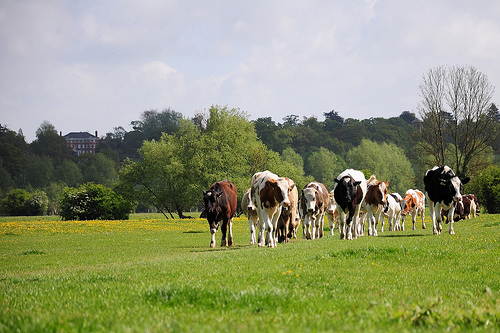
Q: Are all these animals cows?
A: Yes, all the animals are cows.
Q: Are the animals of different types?
A: No, all the animals are cows.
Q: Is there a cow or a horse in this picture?
A: Yes, there is a cow.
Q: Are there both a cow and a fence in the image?
A: No, there is a cow but no fences.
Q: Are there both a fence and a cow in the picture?
A: No, there is a cow but no fences.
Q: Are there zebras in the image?
A: No, there are no zebras.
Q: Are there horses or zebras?
A: No, there are no zebras or horses.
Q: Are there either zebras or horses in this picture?
A: No, there are no zebras or horses.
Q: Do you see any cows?
A: Yes, there is a cow.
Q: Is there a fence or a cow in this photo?
A: Yes, there is a cow.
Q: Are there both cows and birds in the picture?
A: No, there is a cow but no birds.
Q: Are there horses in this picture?
A: No, there are no horses.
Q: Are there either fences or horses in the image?
A: No, there are no horses or fences.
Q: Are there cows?
A: Yes, there is a cow.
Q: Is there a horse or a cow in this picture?
A: Yes, there is a cow.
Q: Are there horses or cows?
A: Yes, there is a cow.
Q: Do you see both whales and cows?
A: No, there is a cow but no whales.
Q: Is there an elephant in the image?
A: No, there are no elephants.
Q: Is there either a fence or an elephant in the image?
A: No, there are no elephants or fences.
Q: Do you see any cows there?
A: Yes, there is a cow.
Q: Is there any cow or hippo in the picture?
A: Yes, there is a cow.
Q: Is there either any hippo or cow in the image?
A: Yes, there is a cow.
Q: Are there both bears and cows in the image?
A: No, there is a cow but no bears.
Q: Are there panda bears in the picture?
A: No, there are no panda bears.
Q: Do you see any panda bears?
A: No, there are no panda bears.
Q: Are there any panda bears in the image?
A: No, there are no panda bears.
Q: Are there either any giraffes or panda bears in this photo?
A: No, there are no panda bears or giraffes.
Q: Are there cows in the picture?
A: Yes, there is a cow.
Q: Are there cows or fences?
A: Yes, there is a cow.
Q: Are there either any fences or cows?
A: Yes, there is a cow.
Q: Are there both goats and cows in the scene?
A: No, there is a cow but no goats.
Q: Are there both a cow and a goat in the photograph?
A: No, there is a cow but no goats.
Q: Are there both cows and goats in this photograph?
A: No, there is a cow but no goats.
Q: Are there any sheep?
A: No, there are no sheep.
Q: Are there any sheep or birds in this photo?
A: No, there are no sheep or birds.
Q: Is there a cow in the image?
A: Yes, there is a cow.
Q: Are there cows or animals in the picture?
A: Yes, there is a cow.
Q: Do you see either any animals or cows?
A: Yes, there is a cow.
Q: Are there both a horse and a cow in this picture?
A: No, there is a cow but no horses.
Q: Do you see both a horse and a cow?
A: No, there is a cow but no horses.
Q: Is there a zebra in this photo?
A: No, there are no zebras.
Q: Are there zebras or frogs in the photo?
A: No, there are no zebras or frogs.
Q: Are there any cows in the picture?
A: Yes, there is a cow.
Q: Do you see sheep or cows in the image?
A: Yes, there is a cow.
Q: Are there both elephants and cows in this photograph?
A: No, there is a cow but no elephants.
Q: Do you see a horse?
A: No, there are no horses.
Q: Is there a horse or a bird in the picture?
A: No, there are no horses or birds.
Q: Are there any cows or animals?
A: Yes, there is a cow.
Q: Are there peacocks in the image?
A: No, there are no peacocks.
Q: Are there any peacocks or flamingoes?
A: No, there are no peacocks or flamingoes.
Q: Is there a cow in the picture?
A: Yes, there is a cow.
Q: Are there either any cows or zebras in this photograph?
A: Yes, there is a cow.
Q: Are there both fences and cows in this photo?
A: No, there is a cow but no fences.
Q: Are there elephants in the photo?
A: No, there are no elephants.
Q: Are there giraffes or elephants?
A: No, there are no elephants or giraffes.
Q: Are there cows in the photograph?
A: Yes, there is a cow.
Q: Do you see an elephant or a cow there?
A: Yes, there is a cow.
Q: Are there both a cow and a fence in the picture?
A: No, there is a cow but no fences.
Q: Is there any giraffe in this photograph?
A: No, there are no giraffes.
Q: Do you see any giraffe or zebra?
A: No, there are no giraffes or zebras.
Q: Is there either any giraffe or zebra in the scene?
A: No, there are no giraffes or zebras.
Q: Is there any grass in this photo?
A: Yes, there is grass.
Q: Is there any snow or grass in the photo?
A: Yes, there is grass.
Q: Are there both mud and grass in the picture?
A: No, there is grass but no mud.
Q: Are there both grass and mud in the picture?
A: No, there is grass but no mud.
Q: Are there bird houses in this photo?
A: No, there are no bird houses.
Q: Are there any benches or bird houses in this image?
A: No, there are no bird houses or benches.